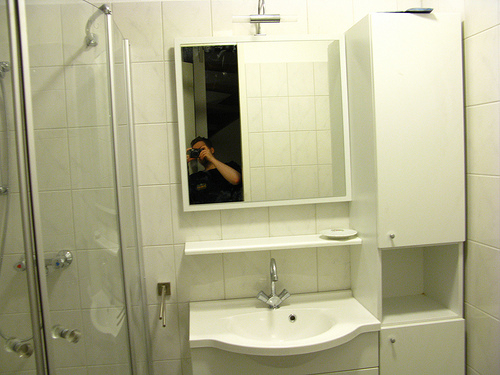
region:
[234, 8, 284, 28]
a light over a mirror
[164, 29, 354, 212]
a mirror over a sink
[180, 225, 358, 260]
a white shelf over a sink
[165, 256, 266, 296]
a white tile wall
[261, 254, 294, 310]
a faucet on a sink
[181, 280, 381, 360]
a white bathroom sink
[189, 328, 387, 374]
a drawer under a sink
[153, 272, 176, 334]
a towel rod next to a sink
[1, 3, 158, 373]
glas doors on a shower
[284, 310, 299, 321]
an overflow drain on a sink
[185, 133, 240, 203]
person holding a black camera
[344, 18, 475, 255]
long white cabinet in the corner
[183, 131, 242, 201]
person taking a photo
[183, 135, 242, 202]
reflection of a person in the mirror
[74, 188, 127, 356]
reflection in the glass shower door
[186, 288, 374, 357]
bright white sink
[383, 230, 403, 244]
tiny silver cabinet handle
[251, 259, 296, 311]
tall white spout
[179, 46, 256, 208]
tal and thin mirror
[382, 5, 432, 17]
something thin hanging off of the top of the cabinet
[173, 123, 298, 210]
man is taking photo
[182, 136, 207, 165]
the camera is black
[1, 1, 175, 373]
shower door made of glass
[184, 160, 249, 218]
man wearing black shirt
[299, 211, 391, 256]
soap dish on counter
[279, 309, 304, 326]
silver hole in sink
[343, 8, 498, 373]
white cabinets next to sink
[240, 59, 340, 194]
wall is reflected in mirror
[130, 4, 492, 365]
the wall is tiled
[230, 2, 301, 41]
light hanging above mirror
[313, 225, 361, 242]
soap on a shelf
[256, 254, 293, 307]
the silver faucet on a sink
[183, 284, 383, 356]
a white sink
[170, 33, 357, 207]
a mirror above a sink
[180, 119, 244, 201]
the reflection of a man in a mirror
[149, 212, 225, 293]
a white tile wall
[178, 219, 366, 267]
a white shelf above a sink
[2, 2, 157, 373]
a glass shower door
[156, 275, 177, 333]
a towel rod by a sink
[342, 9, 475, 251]
a cupboard in a bathroom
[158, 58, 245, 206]
Man in mirror taking a picture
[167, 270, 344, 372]
White porcelain sink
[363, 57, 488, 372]
White cabinets beside of sink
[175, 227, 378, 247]
White shelf above sink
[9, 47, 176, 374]
Clear shower door clean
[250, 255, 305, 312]
Silver sink faucet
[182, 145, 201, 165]
Black camera pointed at mirror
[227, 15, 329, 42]
Light above the mirror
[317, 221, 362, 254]
Soap dish on shelf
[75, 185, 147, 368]
shelf inside of shower